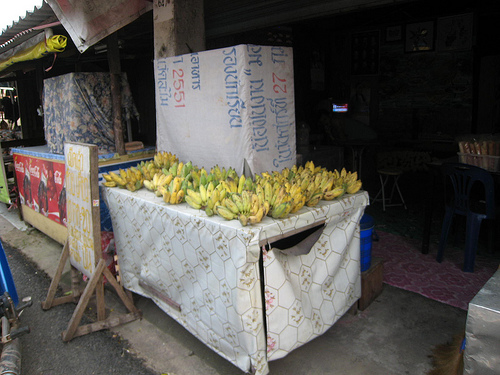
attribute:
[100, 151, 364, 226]
bananas — green, yellow, in bunches, greenish, yellowish, delicious, edible, plentiful, short, unripe, tasty, displayed, many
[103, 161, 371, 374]
table — display table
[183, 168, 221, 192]
bananas — green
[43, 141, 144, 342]
sign — price for bananas, wood, wooden, sale sign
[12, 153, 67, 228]
poster — coca cola sign, red, for coca cola, coca cola poster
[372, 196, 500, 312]
rug — floral, pink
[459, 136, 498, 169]
bread — wrapped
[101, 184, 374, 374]
tablecloth — patterned, white, honeycomb patterned, gold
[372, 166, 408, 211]
chair — folding, white, old, small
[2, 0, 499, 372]
market — empty, outdoor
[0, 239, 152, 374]
road — paved, dark blue, rough, blacktop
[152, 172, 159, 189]
banana — yellow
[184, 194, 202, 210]
banana — yellow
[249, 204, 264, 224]
banana — yellow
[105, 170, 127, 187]
banana — yellow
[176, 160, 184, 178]
banana — yellow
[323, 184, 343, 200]
banana — ripe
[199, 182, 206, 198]
banana — ripe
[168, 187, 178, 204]
banana — ripe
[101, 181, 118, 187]
banana — ripe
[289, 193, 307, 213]
banana — ripe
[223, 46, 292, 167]
font — in caps, blue, asian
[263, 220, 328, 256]
rip — black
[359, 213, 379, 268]
pail — blue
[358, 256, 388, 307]
box — wooden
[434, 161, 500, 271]
chair — blue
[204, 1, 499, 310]
bar — closed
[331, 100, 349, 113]
screen — lit, electronic, on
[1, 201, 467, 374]
floor — concrete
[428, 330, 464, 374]
broom — brown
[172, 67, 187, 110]
lettering — 2551, sideways